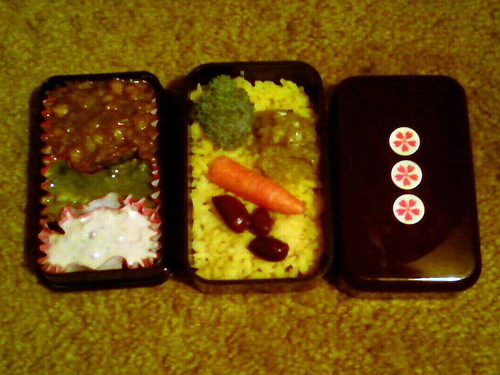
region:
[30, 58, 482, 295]
lunch boxes full of food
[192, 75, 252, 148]
a large piece of broccoli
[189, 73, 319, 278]
a tray of rice and veggies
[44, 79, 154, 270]
a tray full of dips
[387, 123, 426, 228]
flower stickers on a box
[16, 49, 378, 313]
food in trays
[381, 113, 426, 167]
round sticker on a black surface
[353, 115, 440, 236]
three stickers on the black surface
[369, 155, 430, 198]
middle sticker on object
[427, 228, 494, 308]
corner of the black object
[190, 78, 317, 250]
food in the tray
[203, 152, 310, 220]
orange carrot in the food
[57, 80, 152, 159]
brown food in the tray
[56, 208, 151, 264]
white sauce in tray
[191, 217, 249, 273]
yellow food under carrot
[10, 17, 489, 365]
containers on gold carpeting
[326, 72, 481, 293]
closed container with three white stickers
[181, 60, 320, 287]
yellow rice under with vegetables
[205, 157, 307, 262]
red beans next to carrot end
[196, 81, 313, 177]
broccoli floret next to sauteed onion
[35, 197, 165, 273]
creamy white dressing in paper container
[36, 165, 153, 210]
creamy green dressing in paper container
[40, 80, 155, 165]
spicy red condiment in paper container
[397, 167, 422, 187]
the design is orange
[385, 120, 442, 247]
the stickers are white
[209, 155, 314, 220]
carrot on the rice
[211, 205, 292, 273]
olives on the rice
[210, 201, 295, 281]
the olives are dark green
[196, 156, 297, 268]
carrot beside the olive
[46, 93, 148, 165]
beans in the dish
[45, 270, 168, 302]
the dish is black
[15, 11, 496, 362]
3 trays on carpet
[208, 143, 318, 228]
this is a carrot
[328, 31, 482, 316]
this is a black lid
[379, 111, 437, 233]
white decal on lid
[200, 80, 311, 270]
rice in a container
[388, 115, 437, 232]
red flowers on decal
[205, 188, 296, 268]
three olives on rice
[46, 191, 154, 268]
white sauce on container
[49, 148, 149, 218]
green sauce in container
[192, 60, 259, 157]
green item on rice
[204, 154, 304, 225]
a short thick carrot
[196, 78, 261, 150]
some green curry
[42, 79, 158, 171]
some beans with green sauce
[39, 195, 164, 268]
shredded cabbage with white sauce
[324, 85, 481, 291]
the box is black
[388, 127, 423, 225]
white and red logo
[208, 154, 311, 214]
the carrot is orange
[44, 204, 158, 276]
the food is white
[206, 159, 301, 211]
A orange carrot in the bowl.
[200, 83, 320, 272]
Food in the bowl.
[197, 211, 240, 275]
Yellow rice in the black bowl.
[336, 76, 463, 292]
The container is black.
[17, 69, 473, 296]
Three containers on the table.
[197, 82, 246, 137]
Green food on top of the yellow rice.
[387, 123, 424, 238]
Three white circles on top of the container.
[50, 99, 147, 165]
Beans soup in the container.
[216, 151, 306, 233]
A carrot on top of the yellow rice.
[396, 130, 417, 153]
A red flower in the white circle.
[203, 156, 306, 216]
A carrot in a dish